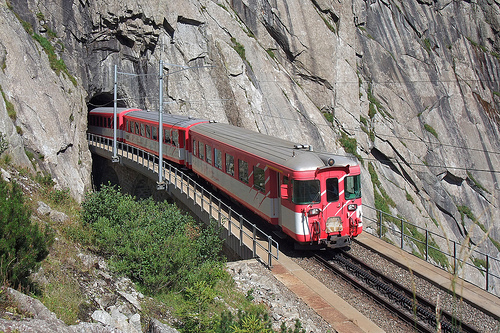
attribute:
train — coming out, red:
[85, 103, 367, 255]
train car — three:
[89, 106, 142, 141]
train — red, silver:
[86, 85, 356, 230]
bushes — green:
[81, 181, 213, 308]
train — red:
[140, 106, 430, 286]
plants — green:
[375, 191, 455, 274]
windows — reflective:
[192, 140, 290, 188]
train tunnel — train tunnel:
[82, 76, 130, 158]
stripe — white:
[153, 148, 314, 233]